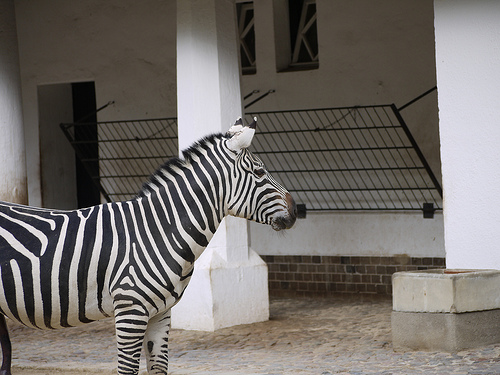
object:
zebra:
[3, 109, 299, 375]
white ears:
[225, 116, 259, 153]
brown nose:
[286, 191, 301, 222]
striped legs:
[142, 320, 175, 375]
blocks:
[389, 265, 499, 314]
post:
[433, 1, 500, 277]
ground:
[0, 287, 499, 375]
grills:
[101, 101, 442, 221]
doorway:
[33, 73, 106, 208]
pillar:
[171, 1, 272, 332]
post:
[1, 1, 33, 203]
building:
[0, 1, 500, 355]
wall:
[17, 0, 449, 298]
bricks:
[388, 307, 500, 354]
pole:
[400, 85, 438, 111]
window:
[269, 1, 326, 79]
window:
[235, 2, 262, 79]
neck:
[136, 140, 219, 259]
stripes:
[140, 196, 185, 277]